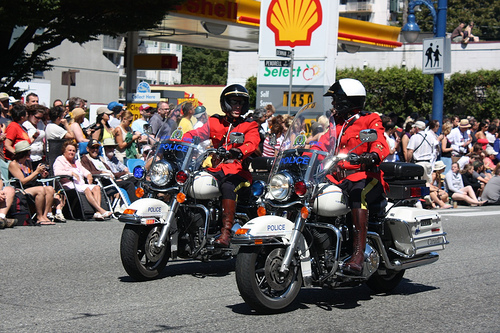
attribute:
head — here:
[216, 74, 273, 122]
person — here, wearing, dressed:
[211, 105, 263, 189]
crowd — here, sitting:
[43, 111, 208, 198]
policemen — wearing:
[152, 41, 371, 190]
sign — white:
[261, 21, 320, 52]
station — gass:
[161, 32, 345, 112]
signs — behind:
[259, 9, 390, 142]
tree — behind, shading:
[43, 8, 133, 70]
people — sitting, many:
[389, 117, 463, 161]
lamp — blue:
[416, 8, 477, 132]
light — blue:
[387, 5, 439, 31]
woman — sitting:
[51, 146, 119, 211]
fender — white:
[126, 169, 181, 232]